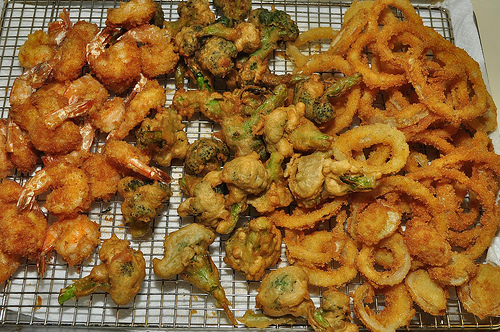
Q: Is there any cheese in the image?
A: No, there is no cheese.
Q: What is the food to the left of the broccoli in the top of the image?
A: The food is shrimp.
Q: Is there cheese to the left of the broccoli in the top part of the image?
A: No, there is shrimp to the left of the broccoli.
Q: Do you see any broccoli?
A: Yes, there is broccoli.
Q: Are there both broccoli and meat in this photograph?
A: No, there is broccoli but no meat.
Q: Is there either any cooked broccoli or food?
A: Yes, there is cooked broccoli.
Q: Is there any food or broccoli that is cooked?
A: Yes, the broccoli is cooked.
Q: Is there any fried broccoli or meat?
A: Yes, there is fried broccoli.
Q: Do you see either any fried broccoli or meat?
A: Yes, there is fried broccoli.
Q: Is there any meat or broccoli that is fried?
A: Yes, the broccoli is fried.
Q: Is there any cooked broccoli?
A: Yes, there is cooked broccoli.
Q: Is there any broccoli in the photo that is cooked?
A: Yes, there is broccoli that is cooked.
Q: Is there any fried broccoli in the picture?
A: Yes, there is fried broccoli.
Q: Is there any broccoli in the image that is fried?
A: Yes, there is broccoli that is fried.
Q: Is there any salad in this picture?
A: No, there is no salad.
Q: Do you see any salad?
A: No, there is no salad.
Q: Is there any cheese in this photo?
A: No, there is no cheese.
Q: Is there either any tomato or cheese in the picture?
A: No, there are no cheese or tomatoes.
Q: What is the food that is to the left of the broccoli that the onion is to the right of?
A: The food is shrimp.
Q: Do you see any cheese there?
A: No, there is no cheese.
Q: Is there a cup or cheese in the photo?
A: No, there are no cheese or cups.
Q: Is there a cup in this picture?
A: No, there are no cups.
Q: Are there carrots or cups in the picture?
A: No, there are no cups or carrots.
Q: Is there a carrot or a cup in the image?
A: No, there are no cups or carrots.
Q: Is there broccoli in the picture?
A: Yes, there is broccoli.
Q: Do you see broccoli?
A: Yes, there is broccoli.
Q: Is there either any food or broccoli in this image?
A: Yes, there is broccoli.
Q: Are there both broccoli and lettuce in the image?
A: No, there is broccoli but no lettuce.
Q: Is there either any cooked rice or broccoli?
A: Yes, there is cooked broccoli.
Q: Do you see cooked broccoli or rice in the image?
A: Yes, there is cooked broccoli.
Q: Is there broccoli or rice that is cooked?
A: Yes, the broccoli is cooked.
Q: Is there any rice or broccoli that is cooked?
A: Yes, the broccoli is cooked.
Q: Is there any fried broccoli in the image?
A: Yes, there is fried broccoli.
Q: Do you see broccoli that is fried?
A: Yes, there is broccoli that is fried.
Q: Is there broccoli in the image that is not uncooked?
A: Yes, there is fried broccoli.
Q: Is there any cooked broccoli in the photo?
A: Yes, there is cooked broccoli.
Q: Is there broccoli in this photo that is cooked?
A: Yes, there is broccoli that is cooked.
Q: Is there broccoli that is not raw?
A: Yes, there is cooked broccoli.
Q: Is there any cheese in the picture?
A: No, there is no cheese.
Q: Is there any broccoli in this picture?
A: Yes, there is broccoli.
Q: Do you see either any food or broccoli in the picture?
A: Yes, there is broccoli.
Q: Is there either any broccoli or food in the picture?
A: Yes, there is broccoli.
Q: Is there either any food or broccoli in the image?
A: Yes, there is broccoli.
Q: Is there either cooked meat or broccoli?
A: Yes, there is cooked broccoli.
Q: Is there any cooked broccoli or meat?
A: Yes, there is cooked broccoli.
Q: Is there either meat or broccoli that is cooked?
A: Yes, the broccoli is cooked.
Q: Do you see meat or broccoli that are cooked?
A: Yes, the broccoli is cooked.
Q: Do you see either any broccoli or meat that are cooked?
A: Yes, the broccoli is cooked.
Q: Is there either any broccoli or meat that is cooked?
A: Yes, the broccoli is cooked.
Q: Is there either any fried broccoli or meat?
A: Yes, there is fried broccoli.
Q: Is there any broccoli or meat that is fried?
A: Yes, the broccoli is fried.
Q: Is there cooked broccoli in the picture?
A: Yes, there is cooked broccoli.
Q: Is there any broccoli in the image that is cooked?
A: Yes, there is broccoli that is cooked.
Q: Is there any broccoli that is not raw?
A: Yes, there is cooked broccoli.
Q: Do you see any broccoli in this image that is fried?
A: Yes, there is broccoli that is fried.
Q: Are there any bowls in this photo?
A: No, there are no bowls.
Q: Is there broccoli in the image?
A: Yes, there is broccoli.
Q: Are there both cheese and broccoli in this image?
A: No, there is broccoli but no cheese.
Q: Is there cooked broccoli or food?
A: Yes, there is cooked broccoli.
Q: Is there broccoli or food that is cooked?
A: Yes, the broccoli is cooked.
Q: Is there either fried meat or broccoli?
A: Yes, there is fried broccoli.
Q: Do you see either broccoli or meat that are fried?
A: Yes, the broccoli is fried.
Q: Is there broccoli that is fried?
A: Yes, there is broccoli that is fried.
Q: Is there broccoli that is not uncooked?
A: Yes, there is fried broccoli.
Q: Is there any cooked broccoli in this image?
A: Yes, there is cooked broccoli.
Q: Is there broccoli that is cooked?
A: Yes, there is broccoli that is cooked.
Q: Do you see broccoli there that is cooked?
A: Yes, there is broccoli that is cooked.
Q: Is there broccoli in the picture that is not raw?
A: Yes, there is cooked broccoli.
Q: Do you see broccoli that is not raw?
A: Yes, there is cooked broccoli.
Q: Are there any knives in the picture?
A: No, there are no knives.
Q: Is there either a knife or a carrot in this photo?
A: No, there are no knives or carrots.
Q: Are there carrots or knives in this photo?
A: No, there are no knives or carrots.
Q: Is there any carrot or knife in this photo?
A: No, there are no knives or carrots.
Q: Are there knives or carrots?
A: No, there are no knives or carrots.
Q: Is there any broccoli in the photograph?
A: Yes, there is broccoli.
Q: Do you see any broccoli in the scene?
A: Yes, there is broccoli.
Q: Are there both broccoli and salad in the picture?
A: No, there is broccoli but no salad.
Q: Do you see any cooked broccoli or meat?
A: Yes, there is cooked broccoli.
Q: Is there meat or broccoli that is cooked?
A: Yes, the broccoli is cooked.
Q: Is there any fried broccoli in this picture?
A: Yes, there is fried broccoli.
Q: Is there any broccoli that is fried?
A: Yes, there is broccoli that is fried.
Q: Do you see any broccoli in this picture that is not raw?
A: Yes, there is fried broccoli.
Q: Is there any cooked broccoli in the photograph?
A: Yes, there is cooked broccoli.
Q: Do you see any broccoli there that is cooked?
A: Yes, there is broccoli that is cooked.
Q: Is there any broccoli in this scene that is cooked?
A: Yes, there is broccoli that is cooked.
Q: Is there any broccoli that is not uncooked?
A: Yes, there is cooked broccoli.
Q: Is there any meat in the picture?
A: No, there is no meat.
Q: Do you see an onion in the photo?
A: Yes, there is an onion.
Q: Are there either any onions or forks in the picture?
A: Yes, there is an onion.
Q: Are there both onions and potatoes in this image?
A: No, there is an onion but no potatoes.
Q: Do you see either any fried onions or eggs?
A: Yes, there is a fried onion.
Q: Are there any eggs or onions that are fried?
A: Yes, the onion is fried.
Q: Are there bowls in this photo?
A: No, there are no bowls.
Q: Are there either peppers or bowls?
A: No, there are no bowls or peppers.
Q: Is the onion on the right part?
A: Yes, the onion is on the right of the image.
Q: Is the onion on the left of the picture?
A: No, the onion is on the right of the image.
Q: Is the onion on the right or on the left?
A: The onion is on the right of the image.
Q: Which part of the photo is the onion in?
A: The onion is on the right of the image.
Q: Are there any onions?
A: Yes, there is an onion.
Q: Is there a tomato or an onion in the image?
A: Yes, there is an onion.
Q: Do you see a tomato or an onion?
A: Yes, there is an onion.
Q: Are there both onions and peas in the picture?
A: No, there is an onion but no peas.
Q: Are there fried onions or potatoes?
A: Yes, there is a fried onion.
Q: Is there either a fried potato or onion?
A: Yes, there is a fried onion.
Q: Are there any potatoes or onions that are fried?
A: Yes, the onion is fried.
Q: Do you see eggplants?
A: No, there are no eggplants.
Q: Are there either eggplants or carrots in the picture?
A: No, there are no eggplants or carrots.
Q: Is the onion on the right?
A: Yes, the onion is on the right of the image.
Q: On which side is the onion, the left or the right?
A: The onion is on the right of the image.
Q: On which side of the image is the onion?
A: The onion is on the right of the image.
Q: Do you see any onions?
A: Yes, there is an onion.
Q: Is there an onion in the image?
A: Yes, there is an onion.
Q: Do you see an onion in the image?
A: Yes, there is an onion.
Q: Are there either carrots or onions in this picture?
A: Yes, there is an onion.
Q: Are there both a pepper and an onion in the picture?
A: No, there is an onion but no peppers.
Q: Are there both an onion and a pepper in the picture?
A: No, there is an onion but no peppers.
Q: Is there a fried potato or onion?
A: Yes, there is a fried onion.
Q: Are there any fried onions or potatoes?
A: Yes, there is a fried onion.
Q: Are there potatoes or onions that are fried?
A: Yes, the onion is fried.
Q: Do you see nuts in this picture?
A: No, there are no nuts.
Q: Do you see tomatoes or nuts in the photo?
A: No, there are no nuts or tomatoes.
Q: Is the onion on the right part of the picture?
A: Yes, the onion is on the right of the image.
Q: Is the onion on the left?
A: No, the onion is on the right of the image.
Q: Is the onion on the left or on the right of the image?
A: The onion is on the right of the image.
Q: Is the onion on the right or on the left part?
A: The onion is on the right of the image.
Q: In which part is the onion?
A: The onion is on the right of the image.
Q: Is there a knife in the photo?
A: No, there are no knives.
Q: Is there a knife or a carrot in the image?
A: No, there are no knives or carrots.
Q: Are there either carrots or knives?
A: No, there are no knives or carrots.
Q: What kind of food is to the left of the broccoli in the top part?
A: The food is shrimp.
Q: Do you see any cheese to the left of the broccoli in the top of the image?
A: No, there is shrimp to the left of the broccoli.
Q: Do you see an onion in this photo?
A: Yes, there is an onion.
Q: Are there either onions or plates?
A: Yes, there is an onion.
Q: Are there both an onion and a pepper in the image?
A: No, there is an onion but no peppers.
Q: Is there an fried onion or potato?
A: Yes, there is a fried onion.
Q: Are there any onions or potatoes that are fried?
A: Yes, the onion is fried.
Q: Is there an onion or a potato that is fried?
A: Yes, the onion is fried.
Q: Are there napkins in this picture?
A: No, there are no napkins.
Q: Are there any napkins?
A: No, there are no napkins.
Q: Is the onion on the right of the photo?
A: Yes, the onion is on the right of the image.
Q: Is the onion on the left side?
A: No, the onion is on the right of the image.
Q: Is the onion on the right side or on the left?
A: The onion is on the right of the image.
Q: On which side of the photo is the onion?
A: The onion is on the right of the image.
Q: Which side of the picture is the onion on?
A: The onion is on the right of the image.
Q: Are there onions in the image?
A: Yes, there is an onion.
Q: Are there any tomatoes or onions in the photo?
A: Yes, there is an onion.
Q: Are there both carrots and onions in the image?
A: No, there is an onion but no carrots.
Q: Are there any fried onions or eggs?
A: Yes, there is a fried onion.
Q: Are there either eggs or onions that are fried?
A: Yes, the onion is fried.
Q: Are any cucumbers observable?
A: No, there are no cucumbers.